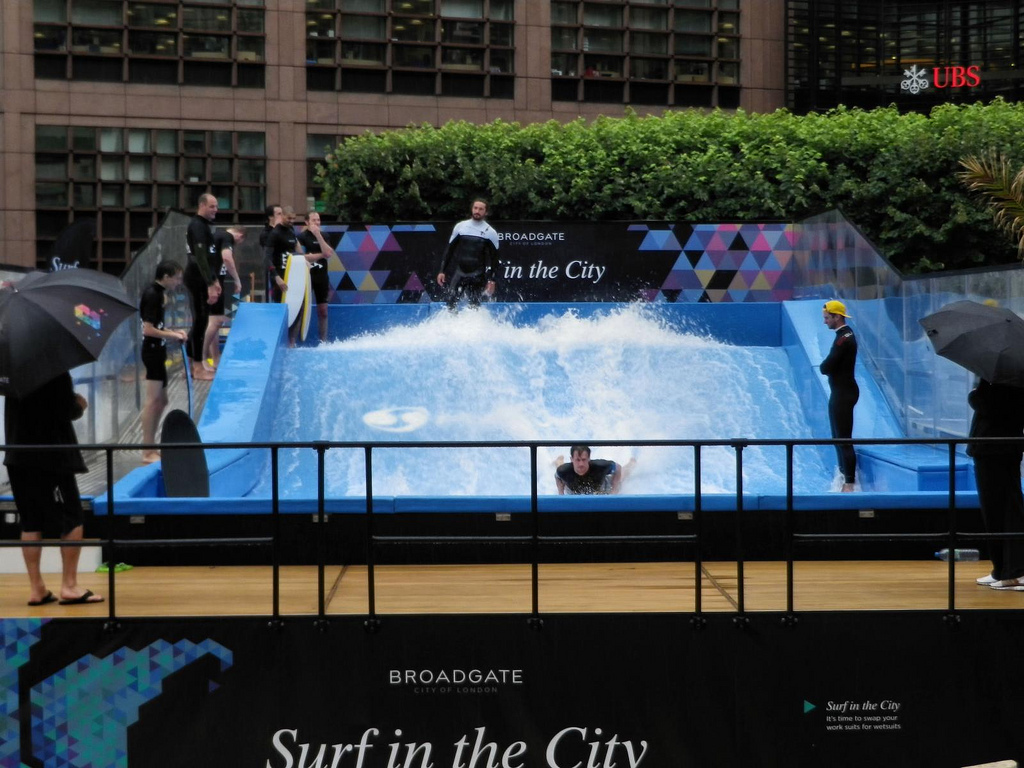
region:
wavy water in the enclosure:
[318, 293, 761, 361]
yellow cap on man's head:
[815, 283, 869, 321]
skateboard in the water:
[148, 388, 228, 497]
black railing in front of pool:
[87, 394, 1020, 644]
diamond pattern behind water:
[629, 179, 904, 300]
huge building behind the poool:
[177, 8, 990, 132]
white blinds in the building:
[81, 100, 211, 218]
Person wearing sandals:
[7, 580, 113, 609]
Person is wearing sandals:
[19, 579, 124, 611]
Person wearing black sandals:
[26, 583, 122, 616]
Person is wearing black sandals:
[23, 576, 113, 612]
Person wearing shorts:
[2, 443, 97, 548]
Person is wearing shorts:
[13, 460, 103, 559]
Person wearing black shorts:
[0, 441, 99, 540]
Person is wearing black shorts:
[2, 459, 94, 539]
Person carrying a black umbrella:
[1, 248, 148, 398]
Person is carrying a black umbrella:
[1, 256, 148, 397]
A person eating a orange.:
[610, 271, 732, 360]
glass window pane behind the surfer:
[32, 122, 62, 145]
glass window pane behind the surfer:
[67, 125, 90, 146]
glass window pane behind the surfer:
[90, 128, 116, 154]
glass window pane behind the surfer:
[152, 125, 176, 146]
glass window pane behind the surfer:
[207, 128, 228, 154]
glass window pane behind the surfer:
[95, 153, 127, 180]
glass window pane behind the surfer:
[127, 154, 150, 184]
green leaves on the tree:
[615, 132, 685, 203]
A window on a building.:
[341, 61, 393, 101]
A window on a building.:
[128, 128, 154, 152]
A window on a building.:
[151, 131, 172, 155]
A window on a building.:
[179, 131, 206, 151]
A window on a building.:
[208, 133, 229, 154]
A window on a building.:
[97, 130, 123, 153]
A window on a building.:
[69, 122, 96, 145]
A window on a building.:
[28, 124, 67, 147]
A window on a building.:
[38, 147, 71, 171]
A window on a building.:
[28, 51, 67, 74]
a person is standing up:
[138, 256, 196, 459]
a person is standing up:
[186, 187, 238, 372]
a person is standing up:
[264, 206, 296, 293]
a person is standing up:
[297, 207, 337, 341]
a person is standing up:
[451, 198, 499, 326]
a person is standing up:
[812, 294, 871, 485]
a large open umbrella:
[925, 288, 1021, 394]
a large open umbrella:
[9, 264, 137, 386]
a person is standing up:
[5, 359, 108, 617]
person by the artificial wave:
[803, 298, 861, 494]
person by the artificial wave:
[443, 197, 507, 309]